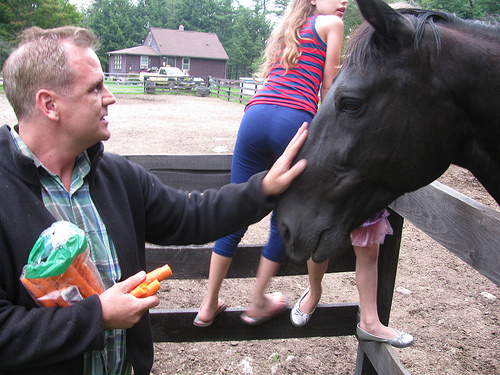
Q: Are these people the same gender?
A: No, they are both male and female.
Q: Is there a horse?
A: Yes, there is a horse.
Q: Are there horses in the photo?
A: Yes, there is a horse.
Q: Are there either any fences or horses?
A: Yes, there is a horse.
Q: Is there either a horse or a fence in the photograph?
A: Yes, there is a horse.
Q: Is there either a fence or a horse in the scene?
A: Yes, there is a horse.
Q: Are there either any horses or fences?
A: Yes, there is a horse.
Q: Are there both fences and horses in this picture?
A: Yes, there are both a horse and a fence.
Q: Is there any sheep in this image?
A: No, there is no sheep.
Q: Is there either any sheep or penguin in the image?
A: No, there are no sheep or penguins.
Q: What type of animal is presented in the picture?
A: The animal is a horse.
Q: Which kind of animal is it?
A: The animal is a horse.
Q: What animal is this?
A: This is a horse.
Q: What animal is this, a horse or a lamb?
A: This is a horse.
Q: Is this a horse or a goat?
A: This is a horse.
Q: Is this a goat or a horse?
A: This is a horse.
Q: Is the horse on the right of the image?
A: Yes, the horse is on the right of the image.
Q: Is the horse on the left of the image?
A: No, the horse is on the right of the image.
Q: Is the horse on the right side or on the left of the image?
A: The horse is on the right of the image.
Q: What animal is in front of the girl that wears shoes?
A: The horse is in front of the girl.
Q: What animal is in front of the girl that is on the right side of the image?
A: The animal is a horse.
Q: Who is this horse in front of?
A: The horse is in front of the girl.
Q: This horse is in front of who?
A: The horse is in front of the girl.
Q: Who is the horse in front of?
A: The horse is in front of the girl.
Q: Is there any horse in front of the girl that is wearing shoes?
A: Yes, there is a horse in front of the girl.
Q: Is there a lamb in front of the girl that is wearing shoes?
A: No, there is a horse in front of the girl.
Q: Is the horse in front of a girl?
A: Yes, the horse is in front of a girl.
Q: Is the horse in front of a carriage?
A: No, the horse is in front of a girl.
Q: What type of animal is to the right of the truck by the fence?
A: The animal is a horse.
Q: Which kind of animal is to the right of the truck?
A: The animal is a horse.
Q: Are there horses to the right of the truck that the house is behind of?
A: Yes, there is a horse to the right of the truck.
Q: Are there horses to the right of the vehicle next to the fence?
A: Yes, there is a horse to the right of the truck.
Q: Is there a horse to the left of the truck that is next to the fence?
A: No, the horse is to the right of the truck.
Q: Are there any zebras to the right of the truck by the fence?
A: No, there is a horse to the right of the truck.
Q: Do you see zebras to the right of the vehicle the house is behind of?
A: No, there is a horse to the right of the truck.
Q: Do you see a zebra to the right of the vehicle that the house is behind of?
A: No, there is a horse to the right of the truck.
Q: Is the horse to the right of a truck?
A: Yes, the horse is to the right of a truck.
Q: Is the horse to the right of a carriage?
A: No, the horse is to the right of a truck.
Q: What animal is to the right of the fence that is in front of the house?
A: The animal is a horse.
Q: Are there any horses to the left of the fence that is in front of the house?
A: No, the horse is to the right of the fence.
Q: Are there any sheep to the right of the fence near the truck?
A: No, there is a horse to the right of the fence.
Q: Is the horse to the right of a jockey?
A: No, the horse is to the right of the fence.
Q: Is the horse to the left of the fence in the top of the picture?
A: No, the horse is to the right of the fence.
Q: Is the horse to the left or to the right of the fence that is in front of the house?
A: The horse is to the right of the fence.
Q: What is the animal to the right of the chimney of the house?
A: The animal is a horse.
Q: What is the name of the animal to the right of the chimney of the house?
A: The animal is a horse.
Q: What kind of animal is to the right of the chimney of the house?
A: The animal is a horse.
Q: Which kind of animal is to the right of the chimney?
A: The animal is a horse.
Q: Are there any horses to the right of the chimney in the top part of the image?
A: Yes, there is a horse to the right of the chimney.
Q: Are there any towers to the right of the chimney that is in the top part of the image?
A: No, there is a horse to the right of the chimney.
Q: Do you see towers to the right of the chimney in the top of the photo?
A: No, there is a horse to the right of the chimney.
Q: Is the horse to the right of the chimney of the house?
A: Yes, the horse is to the right of the chimney.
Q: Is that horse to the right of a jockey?
A: No, the horse is to the right of the chimney.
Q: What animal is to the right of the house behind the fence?
A: The animal is a horse.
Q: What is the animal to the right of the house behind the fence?
A: The animal is a horse.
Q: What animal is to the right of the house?
A: The animal is a horse.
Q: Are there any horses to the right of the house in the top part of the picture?
A: Yes, there is a horse to the right of the house.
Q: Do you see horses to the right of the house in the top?
A: Yes, there is a horse to the right of the house.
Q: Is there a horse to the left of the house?
A: No, the horse is to the right of the house.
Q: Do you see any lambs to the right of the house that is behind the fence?
A: No, there is a horse to the right of the house.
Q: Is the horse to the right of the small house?
A: Yes, the horse is to the right of the house.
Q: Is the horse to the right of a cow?
A: No, the horse is to the right of the house.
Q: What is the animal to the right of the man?
A: The animal is a horse.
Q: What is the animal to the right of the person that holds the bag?
A: The animal is a horse.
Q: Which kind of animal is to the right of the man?
A: The animal is a horse.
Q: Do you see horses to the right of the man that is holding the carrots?
A: Yes, there is a horse to the right of the man.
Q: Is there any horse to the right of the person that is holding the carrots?
A: Yes, there is a horse to the right of the man.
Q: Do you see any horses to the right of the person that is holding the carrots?
A: Yes, there is a horse to the right of the man.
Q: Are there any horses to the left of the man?
A: No, the horse is to the right of the man.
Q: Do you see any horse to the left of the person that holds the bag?
A: No, the horse is to the right of the man.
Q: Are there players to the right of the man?
A: No, there is a horse to the right of the man.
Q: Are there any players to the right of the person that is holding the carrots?
A: No, there is a horse to the right of the man.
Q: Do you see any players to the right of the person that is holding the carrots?
A: No, there is a horse to the right of the man.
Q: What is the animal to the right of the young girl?
A: The animal is a horse.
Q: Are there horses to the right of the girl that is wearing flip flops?
A: Yes, there is a horse to the right of the girl.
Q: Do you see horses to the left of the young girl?
A: No, the horse is to the right of the girl.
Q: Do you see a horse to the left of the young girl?
A: No, the horse is to the right of the girl.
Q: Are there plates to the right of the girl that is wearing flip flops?
A: No, there is a horse to the right of the girl.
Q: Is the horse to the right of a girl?
A: Yes, the horse is to the right of a girl.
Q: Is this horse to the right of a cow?
A: No, the horse is to the right of a girl.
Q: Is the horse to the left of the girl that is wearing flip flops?
A: No, the horse is to the right of the girl.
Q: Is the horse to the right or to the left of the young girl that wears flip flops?
A: The horse is to the right of the girl.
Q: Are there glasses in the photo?
A: No, there are no glasses.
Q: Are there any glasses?
A: No, there are no glasses.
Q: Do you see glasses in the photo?
A: No, there are no glasses.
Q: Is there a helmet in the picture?
A: No, there are no helmets.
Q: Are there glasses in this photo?
A: No, there are no glasses.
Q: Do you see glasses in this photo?
A: No, there are no glasses.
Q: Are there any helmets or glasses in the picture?
A: No, there are no glasses or helmets.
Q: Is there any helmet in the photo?
A: No, there are no helmets.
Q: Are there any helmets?
A: No, there are no helmets.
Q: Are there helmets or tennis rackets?
A: No, there are no helmets or tennis rackets.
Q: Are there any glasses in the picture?
A: No, there are no glasses.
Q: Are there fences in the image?
A: Yes, there is a fence.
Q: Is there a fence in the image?
A: Yes, there is a fence.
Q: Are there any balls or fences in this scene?
A: Yes, there is a fence.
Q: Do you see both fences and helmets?
A: No, there is a fence but no helmets.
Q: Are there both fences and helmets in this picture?
A: No, there is a fence but no helmets.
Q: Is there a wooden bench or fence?
A: Yes, there is a wood fence.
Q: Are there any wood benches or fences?
A: Yes, there is a wood fence.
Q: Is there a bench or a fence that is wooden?
A: Yes, the fence is wooden.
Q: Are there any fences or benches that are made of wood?
A: Yes, the fence is made of wood.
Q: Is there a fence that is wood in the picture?
A: Yes, there is a wood fence.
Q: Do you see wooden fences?
A: Yes, there is a wood fence.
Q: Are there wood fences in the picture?
A: Yes, there is a wood fence.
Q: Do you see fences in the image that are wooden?
A: Yes, there is a fence that is wooden.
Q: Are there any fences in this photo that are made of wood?
A: Yes, there is a fence that is made of wood.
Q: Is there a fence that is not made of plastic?
A: Yes, there is a fence that is made of wood.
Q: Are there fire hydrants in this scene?
A: No, there are no fire hydrants.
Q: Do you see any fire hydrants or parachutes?
A: No, there are no fire hydrants or parachutes.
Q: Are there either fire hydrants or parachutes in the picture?
A: No, there are no fire hydrants or parachutes.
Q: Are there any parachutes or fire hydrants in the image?
A: No, there are no fire hydrants or parachutes.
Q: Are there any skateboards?
A: No, there are no skateboards.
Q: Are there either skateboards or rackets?
A: No, there are no skateboards or rackets.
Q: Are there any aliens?
A: No, there are no aliens.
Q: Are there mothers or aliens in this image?
A: No, there are no aliens or mothers.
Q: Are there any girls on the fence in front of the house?
A: Yes, there is a girl on the fence.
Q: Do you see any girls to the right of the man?
A: Yes, there is a girl to the right of the man.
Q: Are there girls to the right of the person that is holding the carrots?
A: Yes, there is a girl to the right of the man.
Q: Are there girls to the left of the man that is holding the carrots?
A: No, the girl is to the right of the man.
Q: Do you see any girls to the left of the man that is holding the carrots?
A: No, the girl is to the right of the man.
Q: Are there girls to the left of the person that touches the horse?
A: No, the girl is to the right of the man.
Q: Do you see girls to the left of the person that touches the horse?
A: No, the girl is to the right of the man.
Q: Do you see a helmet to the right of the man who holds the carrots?
A: No, there is a girl to the right of the man.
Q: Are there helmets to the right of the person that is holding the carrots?
A: No, there is a girl to the right of the man.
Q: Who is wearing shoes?
A: The girl is wearing shoes.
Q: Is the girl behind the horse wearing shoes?
A: Yes, the girl is wearing shoes.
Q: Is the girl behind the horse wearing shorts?
A: No, the girl is wearing shoes.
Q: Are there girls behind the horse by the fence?
A: Yes, there is a girl behind the horse.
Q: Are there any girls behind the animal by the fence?
A: Yes, there is a girl behind the horse.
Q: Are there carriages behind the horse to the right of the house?
A: No, there is a girl behind the horse.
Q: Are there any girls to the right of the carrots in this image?
A: Yes, there is a girl to the right of the carrots.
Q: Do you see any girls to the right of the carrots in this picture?
A: Yes, there is a girl to the right of the carrots.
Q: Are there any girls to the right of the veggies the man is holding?
A: Yes, there is a girl to the right of the carrots.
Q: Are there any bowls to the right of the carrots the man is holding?
A: No, there is a girl to the right of the carrots.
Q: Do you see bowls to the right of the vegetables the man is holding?
A: No, there is a girl to the right of the carrots.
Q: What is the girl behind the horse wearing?
A: The girl is wearing shoes.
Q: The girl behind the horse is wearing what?
A: The girl is wearing shoes.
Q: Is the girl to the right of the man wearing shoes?
A: Yes, the girl is wearing shoes.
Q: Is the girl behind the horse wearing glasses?
A: No, the girl is wearing shoes.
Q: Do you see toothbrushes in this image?
A: No, there are no toothbrushes.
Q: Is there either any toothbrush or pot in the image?
A: No, there are no toothbrushes or pots.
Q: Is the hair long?
A: Yes, the hair is long.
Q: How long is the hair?
A: The hair is long.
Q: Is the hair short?
A: No, the hair is long.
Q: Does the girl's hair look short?
A: No, the hair is long.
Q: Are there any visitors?
A: No, there are no visitors.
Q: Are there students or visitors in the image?
A: No, there are no visitors or students.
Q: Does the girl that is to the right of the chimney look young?
A: Yes, the girl is young.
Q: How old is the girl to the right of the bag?
A: The girl is young.